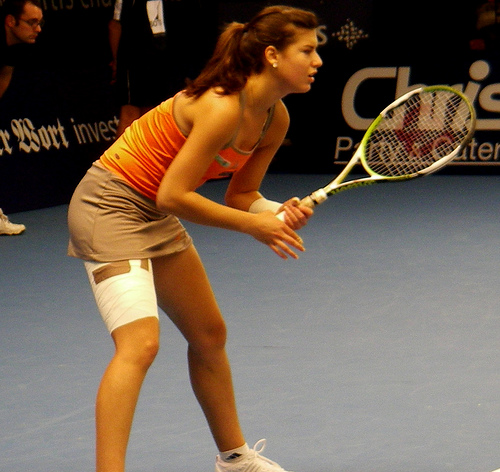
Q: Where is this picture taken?
A: A tennis court.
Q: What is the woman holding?
A: A racket.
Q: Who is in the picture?
A: A man and a woman.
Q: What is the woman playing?
A: Tennis.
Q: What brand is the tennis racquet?
A: Wilson.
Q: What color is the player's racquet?
A: Green and white.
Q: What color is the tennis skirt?
A: Light brown.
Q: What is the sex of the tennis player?
A: Female.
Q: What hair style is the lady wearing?
A: Ponytail.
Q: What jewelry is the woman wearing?
A: Earrings.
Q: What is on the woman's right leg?
A: Ace bandage.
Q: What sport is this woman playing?
A: Tennis.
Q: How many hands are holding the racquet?
A: 2.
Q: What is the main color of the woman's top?
A: Orange.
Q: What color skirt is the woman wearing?
A: Beige.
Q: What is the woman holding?
A: Tennis racket.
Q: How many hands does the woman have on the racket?
A: Two.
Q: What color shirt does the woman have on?
A: Orange.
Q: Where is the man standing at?
A: Behind her crouching.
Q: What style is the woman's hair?
A: Pony tail.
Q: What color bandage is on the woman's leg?
A: White.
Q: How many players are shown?
A: One.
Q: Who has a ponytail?
A: Tennis player.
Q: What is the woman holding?
A: Racket.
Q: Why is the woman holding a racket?
A: To play tennis.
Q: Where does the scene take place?
A: At a tennis game.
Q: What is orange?
A: Woman's tank top.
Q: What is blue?
A: The court.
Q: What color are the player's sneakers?
A: White.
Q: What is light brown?
A: Player's skirt.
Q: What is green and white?
A: Racket.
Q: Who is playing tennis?
A: A woman.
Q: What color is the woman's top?
A: Orange.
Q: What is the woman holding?
A: A racket.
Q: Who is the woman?
A: A tennis player.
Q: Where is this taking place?
A: A tennis match.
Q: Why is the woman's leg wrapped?
A: An injury.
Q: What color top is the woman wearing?
A: An orange top.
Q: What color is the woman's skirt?
A: Tan.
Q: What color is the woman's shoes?
A: White.